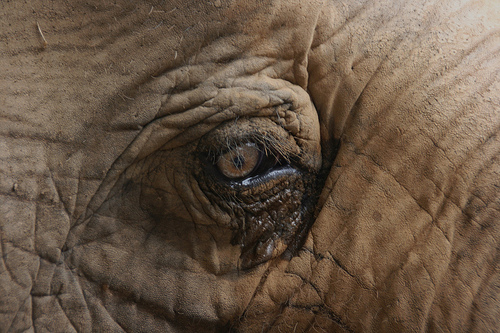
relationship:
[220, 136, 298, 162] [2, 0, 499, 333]
eye lashes belonging to animal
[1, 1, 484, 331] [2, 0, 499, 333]
face belonging to animal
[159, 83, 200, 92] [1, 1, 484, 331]
wrinkle formed on face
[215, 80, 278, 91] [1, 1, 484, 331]
wrinkle formed on face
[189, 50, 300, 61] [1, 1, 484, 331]
wrinkle formed on face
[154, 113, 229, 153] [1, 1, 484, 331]
wrinkle formed on face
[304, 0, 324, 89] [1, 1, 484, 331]
wrinkle formed on face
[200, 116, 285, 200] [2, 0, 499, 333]
eyeball belonging to animal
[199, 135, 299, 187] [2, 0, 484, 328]
eye belonging to animal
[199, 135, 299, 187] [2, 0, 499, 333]
eye belonging to animal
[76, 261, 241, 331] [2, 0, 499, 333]
wrinkle formed on animal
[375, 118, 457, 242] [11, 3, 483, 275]
wrinkle of elephant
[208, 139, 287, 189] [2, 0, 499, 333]
eye of animal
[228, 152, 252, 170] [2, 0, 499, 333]
pupil of animal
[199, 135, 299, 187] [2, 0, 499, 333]
eye of animal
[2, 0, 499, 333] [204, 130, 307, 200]
animal with eye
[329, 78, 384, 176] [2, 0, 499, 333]
wrinkle of animal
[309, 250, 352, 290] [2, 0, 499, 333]
wrinkle of animal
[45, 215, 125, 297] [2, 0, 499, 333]
wrinkle of animal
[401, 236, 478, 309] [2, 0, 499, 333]
wrinkle of animal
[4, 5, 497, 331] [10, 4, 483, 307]
skin of elephant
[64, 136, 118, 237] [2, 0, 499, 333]
wrinkle of animal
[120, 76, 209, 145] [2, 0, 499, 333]
wrinkle of animal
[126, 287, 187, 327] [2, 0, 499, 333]
wrinkle of animal